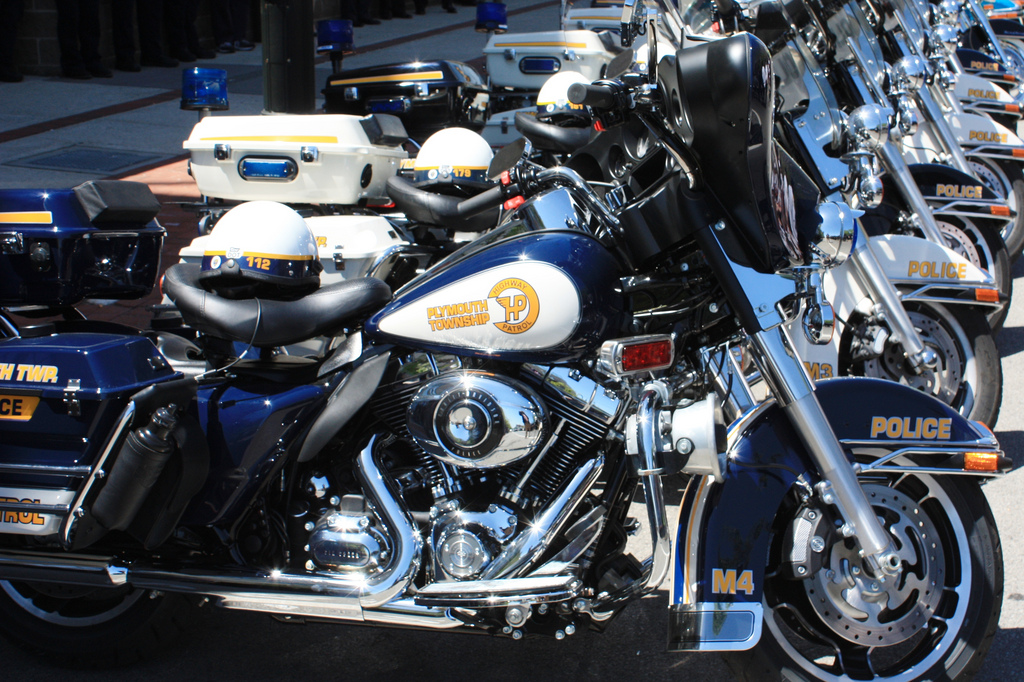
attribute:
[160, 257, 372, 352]
seat — plastic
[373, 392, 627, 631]
motor — chrome